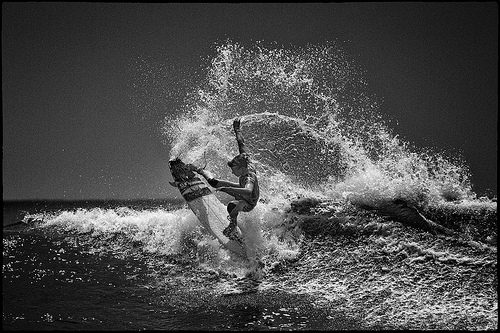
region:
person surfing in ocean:
[139, 120, 274, 272]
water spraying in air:
[182, 53, 310, 127]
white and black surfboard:
[159, 138, 240, 281]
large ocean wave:
[288, 161, 484, 296]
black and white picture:
[30, 21, 471, 310]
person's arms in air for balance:
[177, 102, 293, 259]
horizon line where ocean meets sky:
[13, 186, 148, 209]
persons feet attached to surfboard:
[151, 92, 280, 264]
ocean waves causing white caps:
[57, 196, 182, 237]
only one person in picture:
[77, 23, 470, 304]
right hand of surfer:
[218, 120, 258, 144]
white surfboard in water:
[196, 202, 213, 236]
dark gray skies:
[74, 127, 144, 200]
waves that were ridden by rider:
[358, 162, 465, 230]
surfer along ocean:
[228, 142, 260, 239]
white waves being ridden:
[230, 213, 304, 321]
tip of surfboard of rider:
[173, 177, 204, 208]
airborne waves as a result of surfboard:
[231, 74, 316, 126]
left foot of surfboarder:
[215, 215, 246, 240]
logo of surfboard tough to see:
[224, 223, 279, 258]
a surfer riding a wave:
[152, 109, 267, 275]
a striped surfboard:
[158, 150, 256, 263]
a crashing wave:
[40, 99, 467, 292]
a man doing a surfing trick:
[162, 110, 257, 245]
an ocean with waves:
[1, 176, 163, 330]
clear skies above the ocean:
[8, 7, 490, 79]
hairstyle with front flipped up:
[225, 149, 250, 173]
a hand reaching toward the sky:
[223, 105, 253, 148]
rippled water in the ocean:
[368, 159, 479, 327]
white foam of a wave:
[89, 51, 345, 249]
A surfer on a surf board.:
[168, 127, 325, 265]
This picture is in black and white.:
[45, 52, 440, 331]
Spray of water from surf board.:
[248, 40, 400, 162]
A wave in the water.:
[165, 190, 499, 295]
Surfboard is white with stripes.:
[163, 165, 257, 267]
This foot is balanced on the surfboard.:
[211, 220, 246, 245]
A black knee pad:
[219, 199, 239, 221]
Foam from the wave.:
[29, 205, 157, 254]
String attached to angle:
[198, 152, 215, 176]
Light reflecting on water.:
[21, 231, 106, 297]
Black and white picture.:
[32, 48, 485, 299]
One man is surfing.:
[154, 138, 318, 263]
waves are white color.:
[96, 173, 266, 263]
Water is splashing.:
[207, 52, 369, 164]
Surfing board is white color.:
[168, 148, 258, 266]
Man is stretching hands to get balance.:
[218, 118, 284, 218]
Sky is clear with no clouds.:
[23, 36, 490, 189]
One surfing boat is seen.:
[165, 141, 281, 272]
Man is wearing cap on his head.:
[222, 151, 251, 181]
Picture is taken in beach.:
[32, 76, 487, 311]